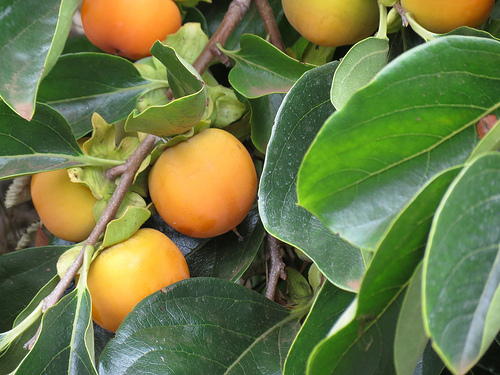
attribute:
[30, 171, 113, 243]
fruit — orange, ripe, yellow, hanging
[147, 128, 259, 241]
fruit — ripe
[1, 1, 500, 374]
tree — up, green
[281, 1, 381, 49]
fruit — colored, yellow, orange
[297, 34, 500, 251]
leaf — shiny, green, large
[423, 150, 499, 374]
leaf — large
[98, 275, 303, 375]
leaf — green, large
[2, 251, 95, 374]
leaves — green, dark, big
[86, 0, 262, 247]
branch — brown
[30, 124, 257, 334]
fruits — round, orange, ripe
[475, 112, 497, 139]
spot — pink